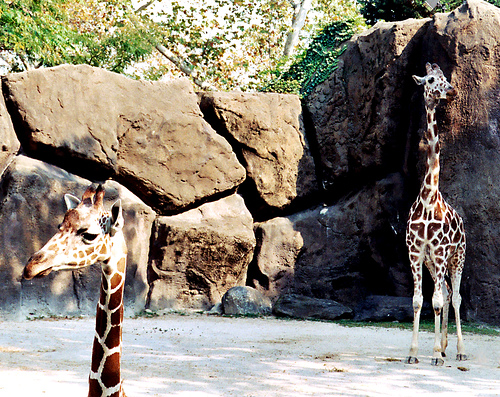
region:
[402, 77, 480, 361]
A tall brown and white giraffe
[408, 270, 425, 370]
A tall brown and white giraffe's feet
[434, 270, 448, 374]
A tall brown and white giraffe's feet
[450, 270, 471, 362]
A tall brown and white giraffe's feet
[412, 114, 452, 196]
A tall brown and white giraffe's neck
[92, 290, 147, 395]
A tall brown and white giraffe's neck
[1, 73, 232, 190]
A big brown stone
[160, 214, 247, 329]
A big brown stone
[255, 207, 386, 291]
A big brown stone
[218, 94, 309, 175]
A big brown stone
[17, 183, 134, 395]
a giraffe's head and neck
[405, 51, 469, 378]
a tall standing giragge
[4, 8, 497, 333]
a large rock wall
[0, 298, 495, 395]
ground is sandy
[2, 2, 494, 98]
trees behind giraffe enclosure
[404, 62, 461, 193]
a giraffe's long neck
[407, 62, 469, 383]
giraffe is brown and white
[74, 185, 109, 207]
giraffe has two small horns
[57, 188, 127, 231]
giraffe's ears are standing upright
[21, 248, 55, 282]
giraffe's snout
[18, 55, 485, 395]
Two giraffes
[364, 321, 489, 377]
The giraffe is standing in dirt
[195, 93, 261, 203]
Big gaps between the rocks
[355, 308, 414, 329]
Small patch of grass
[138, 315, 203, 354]
Many pebbles on the ground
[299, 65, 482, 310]
There rocks are in the shadows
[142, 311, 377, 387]
There are shadows on the ground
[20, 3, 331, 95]
Green plants growing on the rocks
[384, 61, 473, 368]
brown and white giraffe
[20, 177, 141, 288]
giraffe with brown horns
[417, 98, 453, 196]
tall brown and white neck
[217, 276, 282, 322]
big grey rock at base of wall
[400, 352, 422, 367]
black hoof of giraffe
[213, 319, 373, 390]
tan ground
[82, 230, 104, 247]
big black eye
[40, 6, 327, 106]
trees behind rock wall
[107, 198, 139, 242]
brown and white pointed ear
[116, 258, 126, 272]
brown spot on giraffe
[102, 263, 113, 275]
brown spot on giraffe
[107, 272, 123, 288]
brown spot on giraffe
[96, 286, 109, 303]
brown spot on giraffe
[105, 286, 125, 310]
brown spot on giraffe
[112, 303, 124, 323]
brown spot on giraffe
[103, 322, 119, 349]
brown spot on giraffe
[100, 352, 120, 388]
brown spot on giraffe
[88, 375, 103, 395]
brown spot on giraffe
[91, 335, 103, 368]
brown spot on giraffe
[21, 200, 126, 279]
white and brown giraffe head left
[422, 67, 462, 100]
white and brown giraffe head right side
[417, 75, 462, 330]
white and brown big giraffe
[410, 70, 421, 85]
right ear of the giraffe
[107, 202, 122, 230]
left ear of the giraffe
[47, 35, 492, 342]
these are giraffes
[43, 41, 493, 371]
the giraffes are in captivity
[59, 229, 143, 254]
the eyes are black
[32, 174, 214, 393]
the spots are brown and tan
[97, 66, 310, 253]
the rocks are large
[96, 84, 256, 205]
the rocks are flat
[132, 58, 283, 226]
the rocks are jagged